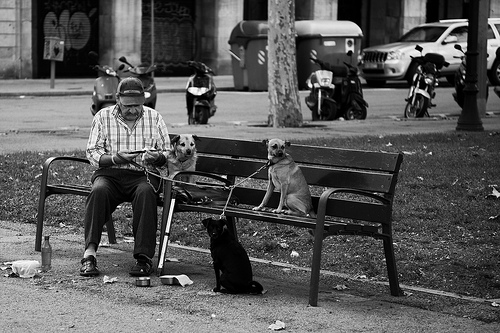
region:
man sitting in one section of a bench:
[31, 76, 402, 304]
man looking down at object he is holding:
[111, 76, 166, 165]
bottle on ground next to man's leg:
[40, 175, 113, 277]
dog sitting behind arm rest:
[167, 133, 227, 198]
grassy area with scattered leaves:
[5, 133, 499, 305]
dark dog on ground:
[200, 213, 265, 303]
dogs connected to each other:
[202, 133, 315, 243]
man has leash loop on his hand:
[111, 146, 142, 178]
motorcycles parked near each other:
[89, 41, 491, 132]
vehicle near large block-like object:
[295, 17, 499, 82]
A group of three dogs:
[162, 128, 314, 307]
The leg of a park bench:
[310, 224, 325, 309]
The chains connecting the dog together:
[147, 164, 269, 216]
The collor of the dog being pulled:
[259, 155, 286, 170]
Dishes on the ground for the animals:
[119, 263, 196, 297]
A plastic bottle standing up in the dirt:
[36, 231, 56, 277]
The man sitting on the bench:
[78, 73, 168, 286]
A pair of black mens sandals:
[75, 251, 155, 278]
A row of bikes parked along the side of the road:
[90, 44, 495, 121]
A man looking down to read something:
[80, 56, 168, 287]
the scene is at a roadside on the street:
[0, 0, 498, 331]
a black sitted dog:
[198, 225, 267, 297]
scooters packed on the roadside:
[178, 56, 225, 128]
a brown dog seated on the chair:
[258, 135, 324, 227]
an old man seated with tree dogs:
[70, 83, 331, 295]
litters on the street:
[3, 244, 63, 289]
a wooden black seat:
[312, 144, 411, 307]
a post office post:
[42, 36, 68, 93]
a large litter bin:
[226, 17, 359, 82]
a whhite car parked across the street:
[361, 13, 471, 80]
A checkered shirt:
[86, 112, 170, 169]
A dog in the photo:
[259, 137, 319, 218]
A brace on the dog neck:
[234, 164, 264, 198]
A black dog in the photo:
[202, 210, 262, 294]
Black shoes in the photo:
[68, 244, 159, 281]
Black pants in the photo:
[77, 173, 160, 250]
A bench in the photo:
[292, 151, 399, 269]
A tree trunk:
[267, 22, 309, 124]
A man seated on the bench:
[72, 75, 171, 272]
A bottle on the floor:
[32, 232, 59, 274]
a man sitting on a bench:
[80, 74, 168, 279]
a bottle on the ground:
[37, 232, 55, 274]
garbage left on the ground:
[99, 273, 197, 288]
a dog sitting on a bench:
[250, 137, 316, 220]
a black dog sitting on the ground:
[200, 211, 265, 296]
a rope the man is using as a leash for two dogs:
[135, 159, 270, 219]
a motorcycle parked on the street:
[401, 44, 449, 118]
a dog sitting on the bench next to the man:
[163, 131, 199, 188]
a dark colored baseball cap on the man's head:
[114, 76, 147, 108]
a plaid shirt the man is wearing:
[85, 106, 172, 157]